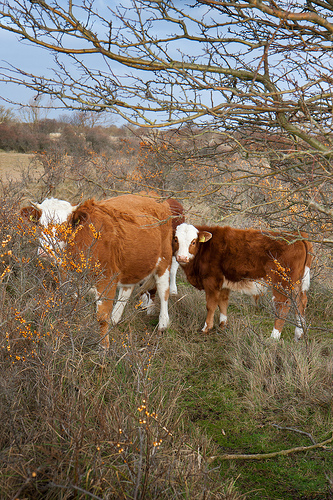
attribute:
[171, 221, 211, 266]
face — white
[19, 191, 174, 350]
cow — mother cow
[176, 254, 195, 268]
nose — pink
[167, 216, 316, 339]
cow — small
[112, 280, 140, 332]
leg — white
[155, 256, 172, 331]
leg — white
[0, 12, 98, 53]
tree branch — skinny, bare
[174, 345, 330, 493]
grass — green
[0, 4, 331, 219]
tree — bare, skinny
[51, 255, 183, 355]
legs — long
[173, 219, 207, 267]
face — white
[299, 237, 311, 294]
tail — short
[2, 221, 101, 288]
leaves — red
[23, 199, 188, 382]
mother cow — brown, white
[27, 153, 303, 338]
cow — brown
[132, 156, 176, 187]
flowers — orange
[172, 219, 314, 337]
calf — brown, white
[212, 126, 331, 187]
skinny branch — bare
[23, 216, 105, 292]
flowers — wild flowers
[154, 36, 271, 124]
branches — gray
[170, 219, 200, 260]
stripe — white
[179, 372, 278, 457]
patch — small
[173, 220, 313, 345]
cow — smaller, brown, baby